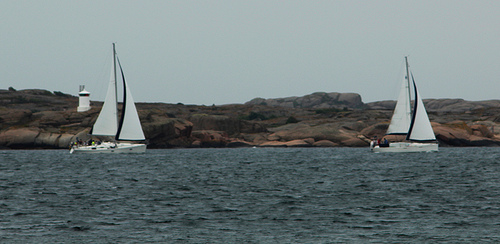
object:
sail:
[407, 71, 437, 141]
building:
[76, 84, 92, 112]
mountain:
[0, 85, 500, 148]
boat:
[66, 42, 146, 155]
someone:
[384, 138, 388, 145]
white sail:
[115, 55, 146, 142]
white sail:
[90, 43, 117, 135]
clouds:
[0, 0, 500, 106]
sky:
[0, 0, 500, 104]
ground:
[0, 86, 500, 148]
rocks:
[0, 86, 500, 150]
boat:
[368, 55, 440, 154]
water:
[0, 146, 500, 244]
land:
[0, 86, 500, 148]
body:
[0, 90, 500, 140]